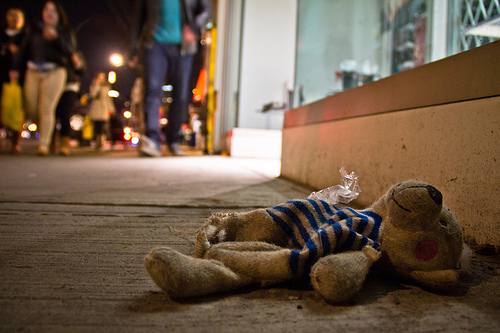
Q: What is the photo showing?
A: It is showing a sidewalk.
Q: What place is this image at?
A: It is at the sidewalk.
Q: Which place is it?
A: It is a sidewalk.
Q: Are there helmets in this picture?
A: No, there are no helmets.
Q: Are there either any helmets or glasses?
A: No, there are no helmets or glasses.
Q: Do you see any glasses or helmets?
A: No, there are no helmets or glasses.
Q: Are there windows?
A: Yes, there is a window.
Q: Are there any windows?
A: Yes, there is a window.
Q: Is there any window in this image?
A: Yes, there is a window.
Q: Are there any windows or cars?
A: Yes, there is a window.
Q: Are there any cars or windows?
A: Yes, there is a window.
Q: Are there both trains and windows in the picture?
A: No, there is a window but no trains.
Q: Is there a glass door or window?
A: Yes, there is a glass window.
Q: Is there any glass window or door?
A: Yes, there is a glass window.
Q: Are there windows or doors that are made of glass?
A: Yes, the window is made of glass.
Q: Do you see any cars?
A: No, there are no cars.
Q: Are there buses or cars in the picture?
A: No, there are no cars or buses.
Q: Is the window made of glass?
A: Yes, the window is made of glass.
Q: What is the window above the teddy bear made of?
A: The window is made of glass.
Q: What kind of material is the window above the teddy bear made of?
A: The window is made of glass.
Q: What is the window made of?
A: The window is made of glass.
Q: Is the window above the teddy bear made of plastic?
A: No, the window is made of glass.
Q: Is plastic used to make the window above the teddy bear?
A: No, the window is made of glass.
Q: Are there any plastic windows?
A: No, there is a window but it is made of glass.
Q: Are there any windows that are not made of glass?
A: No, there is a window but it is made of glass.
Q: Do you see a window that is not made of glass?
A: No, there is a window but it is made of glass.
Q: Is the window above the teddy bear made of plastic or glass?
A: The window is made of glass.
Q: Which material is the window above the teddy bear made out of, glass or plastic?
A: The window is made of glass.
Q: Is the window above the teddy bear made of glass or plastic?
A: The window is made of glass.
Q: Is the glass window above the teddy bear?
A: Yes, the window is above the teddy bear.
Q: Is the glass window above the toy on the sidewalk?
A: Yes, the window is above the teddy bear.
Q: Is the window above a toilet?
A: No, the window is above the teddy bear.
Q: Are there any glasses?
A: No, there are no glasses.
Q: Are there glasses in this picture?
A: No, there are no glasses.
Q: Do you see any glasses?
A: No, there are no glasses.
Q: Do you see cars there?
A: No, there are no cars.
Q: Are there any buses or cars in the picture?
A: No, there are no cars or buses.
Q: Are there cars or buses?
A: No, there are no cars or buses.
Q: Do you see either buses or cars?
A: No, there are no cars or buses.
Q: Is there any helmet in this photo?
A: No, there are no helmets.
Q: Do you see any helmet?
A: No, there are no helmets.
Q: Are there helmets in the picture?
A: No, there are no helmets.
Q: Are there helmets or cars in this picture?
A: No, there are no helmets or cars.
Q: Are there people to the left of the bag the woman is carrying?
A: Yes, there is a person to the left of the bag.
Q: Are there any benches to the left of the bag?
A: No, there is a person to the left of the bag.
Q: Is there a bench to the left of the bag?
A: No, there is a person to the left of the bag.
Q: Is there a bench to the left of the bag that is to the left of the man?
A: No, there is a person to the left of the bag.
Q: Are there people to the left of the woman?
A: Yes, there is a person to the left of the woman.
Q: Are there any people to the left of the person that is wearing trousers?
A: Yes, there is a person to the left of the woman.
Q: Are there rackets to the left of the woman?
A: No, there is a person to the left of the woman.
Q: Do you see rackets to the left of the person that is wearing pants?
A: No, there is a person to the left of the woman.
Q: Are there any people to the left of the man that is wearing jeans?
A: Yes, there is a person to the left of the man.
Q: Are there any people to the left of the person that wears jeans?
A: Yes, there is a person to the left of the man.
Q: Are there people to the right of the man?
A: No, the person is to the left of the man.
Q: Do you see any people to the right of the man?
A: No, the person is to the left of the man.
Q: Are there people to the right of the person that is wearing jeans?
A: No, the person is to the left of the man.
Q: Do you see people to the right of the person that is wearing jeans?
A: No, the person is to the left of the man.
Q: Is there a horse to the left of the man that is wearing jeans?
A: No, there is a person to the left of the man.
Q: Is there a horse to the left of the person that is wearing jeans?
A: No, there is a person to the left of the man.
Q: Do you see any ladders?
A: No, there are no ladders.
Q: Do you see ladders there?
A: No, there are no ladders.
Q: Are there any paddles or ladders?
A: No, there are no ladders or paddles.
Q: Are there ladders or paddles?
A: No, there are no ladders or paddles.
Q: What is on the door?
A: The gate is on the door.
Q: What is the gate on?
A: The gate is on the door.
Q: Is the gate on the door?
A: Yes, the gate is on the door.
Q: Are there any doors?
A: Yes, there is a door.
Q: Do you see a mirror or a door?
A: Yes, there is a door.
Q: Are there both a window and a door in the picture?
A: Yes, there are both a door and a window.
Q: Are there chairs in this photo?
A: No, there are no chairs.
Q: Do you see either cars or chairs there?
A: No, there are no chairs or cars.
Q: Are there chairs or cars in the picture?
A: No, there are no chairs or cars.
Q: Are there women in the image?
A: Yes, there is a woman.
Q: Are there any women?
A: Yes, there is a woman.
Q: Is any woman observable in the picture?
A: Yes, there is a woman.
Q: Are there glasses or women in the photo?
A: Yes, there is a woman.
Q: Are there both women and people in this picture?
A: Yes, there are both a woman and people.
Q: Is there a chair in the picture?
A: No, there are no chairs.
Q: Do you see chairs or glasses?
A: No, there are no chairs or glasses.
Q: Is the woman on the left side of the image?
A: Yes, the woman is on the left of the image.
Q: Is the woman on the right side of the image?
A: No, the woman is on the left of the image.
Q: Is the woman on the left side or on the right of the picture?
A: The woman is on the left of the image.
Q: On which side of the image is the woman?
A: The woman is on the left of the image.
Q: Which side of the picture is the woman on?
A: The woman is on the left of the image.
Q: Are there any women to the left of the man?
A: Yes, there is a woman to the left of the man.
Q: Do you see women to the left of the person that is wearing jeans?
A: Yes, there is a woman to the left of the man.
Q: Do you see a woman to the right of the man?
A: No, the woman is to the left of the man.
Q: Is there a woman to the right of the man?
A: No, the woman is to the left of the man.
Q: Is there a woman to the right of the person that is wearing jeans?
A: No, the woman is to the left of the man.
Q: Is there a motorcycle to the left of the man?
A: No, there is a woman to the left of the man.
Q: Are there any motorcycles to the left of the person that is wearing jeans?
A: No, there is a woman to the left of the man.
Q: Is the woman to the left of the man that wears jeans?
A: Yes, the woman is to the left of the man.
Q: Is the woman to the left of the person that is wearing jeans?
A: Yes, the woman is to the left of the man.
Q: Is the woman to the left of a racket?
A: No, the woman is to the left of the man.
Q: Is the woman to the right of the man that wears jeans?
A: No, the woman is to the left of the man.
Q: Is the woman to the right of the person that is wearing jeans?
A: No, the woman is to the left of the man.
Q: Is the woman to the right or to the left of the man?
A: The woman is to the left of the man.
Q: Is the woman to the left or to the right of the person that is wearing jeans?
A: The woman is to the left of the man.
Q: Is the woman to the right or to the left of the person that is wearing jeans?
A: The woman is to the left of the man.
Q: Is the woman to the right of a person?
A: No, the woman is to the left of a person.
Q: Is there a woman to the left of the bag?
A: Yes, there is a woman to the left of the bag.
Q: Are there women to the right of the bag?
A: No, the woman is to the left of the bag.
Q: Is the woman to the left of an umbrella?
A: No, the woman is to the left of the bag.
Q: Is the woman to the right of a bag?
A: No, the woman is to the left of a bag.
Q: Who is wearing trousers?
A: The woman is wearing trousers.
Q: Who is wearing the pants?
A: The woman is wearing trousers.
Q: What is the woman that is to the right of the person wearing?
A: The woman is wearing pants.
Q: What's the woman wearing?
A: The woman is wearing pants.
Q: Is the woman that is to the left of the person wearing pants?
A: Yes, the woman is wearing pants.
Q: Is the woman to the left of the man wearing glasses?
A: No, the woman is wearing pants.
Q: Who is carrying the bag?
A: The woman is carrying the bag.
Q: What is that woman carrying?
A: The woman is carrying a bag.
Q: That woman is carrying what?
A: The woman is carrying a bag.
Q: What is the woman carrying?
A: The woman is carrying a bag.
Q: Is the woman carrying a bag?
A: Yes, the woman is carrying a bag.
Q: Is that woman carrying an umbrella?
A: No, the woman is carrying a bag.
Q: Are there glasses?
A: No, there are no glasses.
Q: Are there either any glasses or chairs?
A: No, there are no glasses or chairs.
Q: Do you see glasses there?
A: No, there are no glasses.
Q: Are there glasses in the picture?
A: No, there are no glasses.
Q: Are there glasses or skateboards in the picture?
A: No, there are no glasses or skateboards.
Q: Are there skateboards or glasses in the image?
A: No, there are no glasses or skateboards.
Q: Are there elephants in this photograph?
A: No, there are no elephants.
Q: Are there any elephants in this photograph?
A: No, there are no elephants.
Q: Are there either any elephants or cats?
A: No, there are no elephants or cats.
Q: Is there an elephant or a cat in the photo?
A: No, there are no elephants or cats.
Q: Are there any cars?
A: No, there are no cars.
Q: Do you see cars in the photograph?
A: No, there are no cars.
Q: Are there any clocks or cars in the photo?
A: No, there are no cars or clocks.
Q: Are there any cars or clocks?
A: No, there are no cars or clocks.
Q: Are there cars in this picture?
A: No, there are no cars.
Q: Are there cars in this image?
A: No, there are no cars.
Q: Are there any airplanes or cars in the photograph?
A: No, there are no cars or airplanes.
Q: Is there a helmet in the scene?
A: No, there are no helmets.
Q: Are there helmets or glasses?
A: No, there are no helmets or glasses.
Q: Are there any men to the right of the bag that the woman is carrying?
A: Yes, there is a man to the right of the bag.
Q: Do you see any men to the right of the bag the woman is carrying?
A: Yes, there is a man to the right of the bag.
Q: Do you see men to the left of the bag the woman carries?
A: No, the man is to the right of the bag.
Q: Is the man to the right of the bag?
A: Yes, the man is to the right of the bag.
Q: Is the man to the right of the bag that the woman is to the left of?
A: Yes, the man is to the right of the bag.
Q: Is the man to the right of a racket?
A: No, the man is to the right of the bag.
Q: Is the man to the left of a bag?
A: No, the man is to the right of a bag.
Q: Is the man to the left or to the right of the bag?
A: The man is to the right of the bag.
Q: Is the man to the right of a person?
A: Yes, the man is to the right of a person.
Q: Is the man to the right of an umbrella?
A: No, the man is to the right of a person.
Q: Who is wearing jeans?
A: The man is wearing jeans.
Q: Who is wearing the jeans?
A: The man is wearing jeans.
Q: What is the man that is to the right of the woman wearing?
A: The man is wearing jeans.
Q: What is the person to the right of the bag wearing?
A: The man is wearing jeans.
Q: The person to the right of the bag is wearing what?
A: The man is wearing jeans.